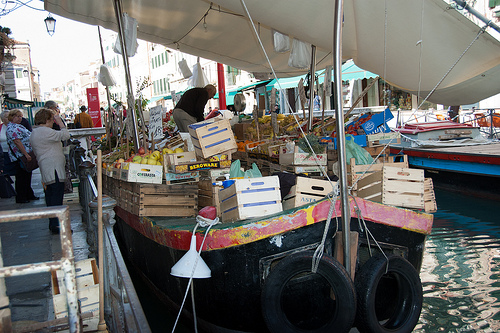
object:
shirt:
[5, 122, 34, 164]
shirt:
[175, 86, 208, 121]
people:
[31, 109, 77, 235]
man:
[172, 84, 217, 133]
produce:
[116, 157, 126, 163]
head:
[35, 108, 55, 129]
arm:
[43, 118, 72, 142]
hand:
[22, 153, 32, 163]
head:
[204, 83, 219, 98]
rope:
[327, 193, 339, 239]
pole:
[333, 0, 351, 271]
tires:
[263, 251, 358, 332]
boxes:
[210, 175, 285, 223]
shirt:
[29, 126, 72, 184]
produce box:
[283, 174, 338, 209]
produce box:
[358, 164, 426, 209]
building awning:
[273, 59, 379, 91]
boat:
[42, 0, 500, 332]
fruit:
[330, 131, 337, 138]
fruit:
[263, 114, 270, 120]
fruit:
[174, 146, 184, 155]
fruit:
[146, 159, 156, 165]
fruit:
[250, 143, 255, 148]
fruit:
[276, 113, 285, 119]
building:
[102, 33, 243, 111]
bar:
[58, 206, 82, 331]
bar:
[1, 203, 68, 223]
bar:
[1, 258, 64, 278]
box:
[116, 163, 165, 183]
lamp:
[43, 11, 57, 37]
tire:
[355, 251, 424, 333]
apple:
[148, 151, 162, 157]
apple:
[131, 155, 141, 162]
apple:
[173, 146, 184, 155]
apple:
[135, 146, 146, 155]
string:
[349, 24, 489, 187]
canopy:
[198, 1, 500, 107]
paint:
[113, 194, 437, 331]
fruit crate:
[422, 179, 437, 213]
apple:
[145, 156, 157, 166]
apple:
[147, 152, 158, 159]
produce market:
[88, 57, 441, 301]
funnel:
[169, 235, 213, 279]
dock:
[0, 158, 124, 333]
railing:
[74, 155, 159, 333]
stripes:
[399, 155, 500, 175]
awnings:
[43, 2, 351, 78]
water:
[413, 201, 500, 333]